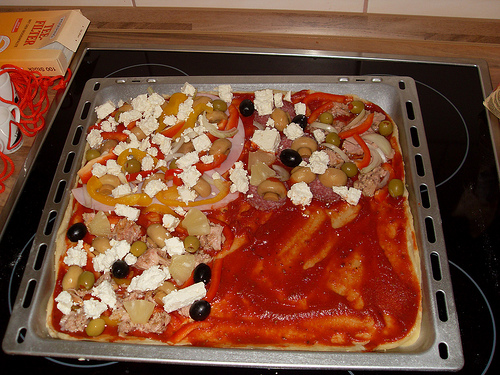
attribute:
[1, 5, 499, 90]
trim — wooden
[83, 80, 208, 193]
cheese — feta, yellow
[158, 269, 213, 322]
cheese — feta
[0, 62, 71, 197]
string — orange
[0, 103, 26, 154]
mugs — white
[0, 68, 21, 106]
mugs — white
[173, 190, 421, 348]
pizza sauce — red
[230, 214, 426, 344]
sauce — red, pizza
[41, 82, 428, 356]
pizza — supreme, square, red, covering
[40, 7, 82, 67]
filters — white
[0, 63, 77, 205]
red string — bright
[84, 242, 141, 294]
cheese — feta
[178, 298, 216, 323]
olive — black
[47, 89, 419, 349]
sauce — smeared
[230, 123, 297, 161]
cheese — feta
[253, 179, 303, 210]
mushroom — large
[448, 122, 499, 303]
stove top — black, clean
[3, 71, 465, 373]
pan — pizza, silver, very thin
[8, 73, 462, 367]
tray — metal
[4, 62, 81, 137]
string — long red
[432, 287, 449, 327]
hole — oval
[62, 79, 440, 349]
pizza — homemade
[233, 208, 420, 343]
tomato sauce — dark red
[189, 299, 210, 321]
olive — black, shiny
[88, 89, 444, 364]
pizza — uncooked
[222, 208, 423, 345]
crust — pizza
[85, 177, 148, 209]
pepper — bell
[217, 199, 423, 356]
section — plain, one